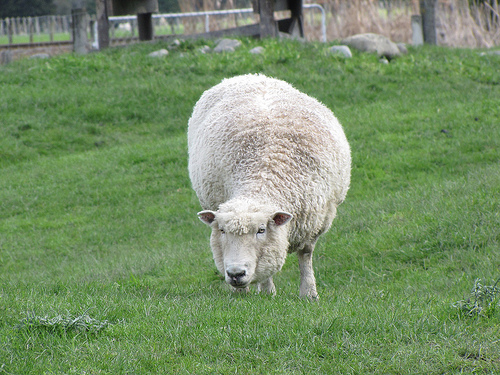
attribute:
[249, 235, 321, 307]
front legs — white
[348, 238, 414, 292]
grass — green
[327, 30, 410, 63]
rocks —  grey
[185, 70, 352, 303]
sheep — white, fluffy, woolly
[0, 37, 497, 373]
grass —  green, green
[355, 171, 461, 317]
grass — green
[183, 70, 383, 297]
sheep — white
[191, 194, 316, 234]
ears — white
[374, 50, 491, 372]
grass — green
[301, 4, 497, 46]
hay — tall, tan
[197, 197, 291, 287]
head — white